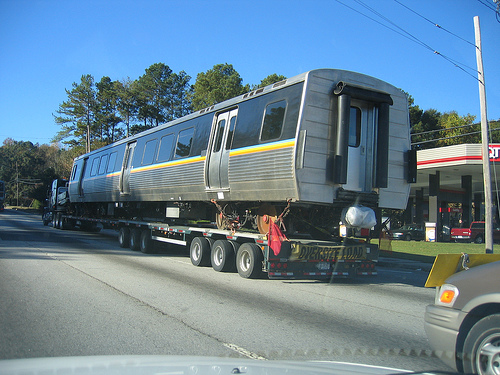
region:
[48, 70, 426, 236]
train car on a flatbed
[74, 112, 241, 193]
doors on the side of the train car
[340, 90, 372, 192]
door on back of train car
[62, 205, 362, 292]
flatbed train car is loaded on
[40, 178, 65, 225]
cab of the flatbed truck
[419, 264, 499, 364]
car behind the flatbed truck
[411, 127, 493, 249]
gas station beside the road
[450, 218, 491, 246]
red truck at the gas station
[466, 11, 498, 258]
utility pole at gas station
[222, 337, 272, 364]
white line painted on the street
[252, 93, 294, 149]
Small window on a train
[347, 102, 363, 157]
Small window on a train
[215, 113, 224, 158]
Small window on a train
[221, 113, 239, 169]
Small window on a train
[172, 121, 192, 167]
Small window on a train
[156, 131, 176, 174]
Small window on a train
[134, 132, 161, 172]
Small window on a train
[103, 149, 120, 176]
Small window on a train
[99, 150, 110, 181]
Small window on a train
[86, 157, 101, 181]
Small window on a train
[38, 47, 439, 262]
a train car on a truck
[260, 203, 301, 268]
a red flag on the back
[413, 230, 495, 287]
yellow sign on front of car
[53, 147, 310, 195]
a yellow stripe on the train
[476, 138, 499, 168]
QT sign at gas station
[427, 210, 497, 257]
a red truck getting gas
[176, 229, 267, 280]
three wheels on back of truck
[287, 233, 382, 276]
Yellow and black sign on back of truck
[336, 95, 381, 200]
a white door on back of train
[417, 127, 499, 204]
white and red awning of gas station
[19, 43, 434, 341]
a metal train and trailer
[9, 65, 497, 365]
trailer with a metal train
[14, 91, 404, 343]
semi truck carrying trailer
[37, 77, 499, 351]
trailer with metal train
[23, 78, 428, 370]
metal train with semi truck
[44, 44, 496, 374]
semi truck near gas station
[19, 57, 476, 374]
semi truck with train near gas station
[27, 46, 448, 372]
semitruck carrying metal train on road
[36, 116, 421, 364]
semitruck on a paved road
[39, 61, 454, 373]
paved road with a metal train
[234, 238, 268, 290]
Wheel of a truck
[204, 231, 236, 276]
Wheel of a truck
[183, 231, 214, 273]
Wheel of a truck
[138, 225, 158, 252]
Wheel of a truck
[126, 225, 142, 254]
Wheel of a truck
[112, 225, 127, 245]
Wheel of a truck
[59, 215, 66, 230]
Wheel of a truck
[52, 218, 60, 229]
Wheel of a truck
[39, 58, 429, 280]
This is a truck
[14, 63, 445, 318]
This is a grey truck